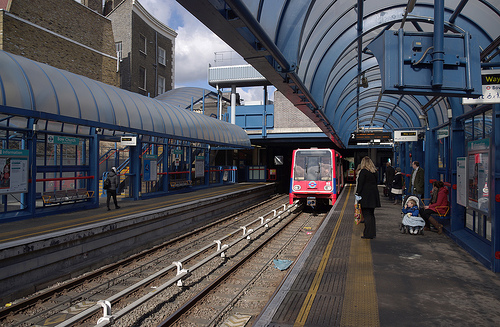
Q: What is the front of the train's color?
A: Red and blue.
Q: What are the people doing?
A: Waiting for the train.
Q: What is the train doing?
A: Arriving.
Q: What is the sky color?
A: Blue.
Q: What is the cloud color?
A: White.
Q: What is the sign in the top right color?
A: Blue.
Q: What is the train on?
A: Tracks.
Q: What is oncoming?
A: A train.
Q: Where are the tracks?
A: On the rail.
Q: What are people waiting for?
A: The train.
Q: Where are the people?
A: On the side of the track.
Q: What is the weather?
A: Partly Cloudy.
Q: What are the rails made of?
A: Metal.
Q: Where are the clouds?
A: In the sky.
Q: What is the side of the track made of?
A: Concrete.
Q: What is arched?
A: The ceiling.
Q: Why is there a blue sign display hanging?
A: Passenger schedule.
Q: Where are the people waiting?
A: Train station.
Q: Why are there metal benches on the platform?
A: Waiting area.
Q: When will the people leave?
A: After train stops.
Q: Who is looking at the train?
A: People at the waiting area.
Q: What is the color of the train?
A: Red.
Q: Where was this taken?
A: Train station.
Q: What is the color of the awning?
A: Blue.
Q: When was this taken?
A: Daytime.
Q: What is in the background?
A: People.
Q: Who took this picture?
A: A photographer.